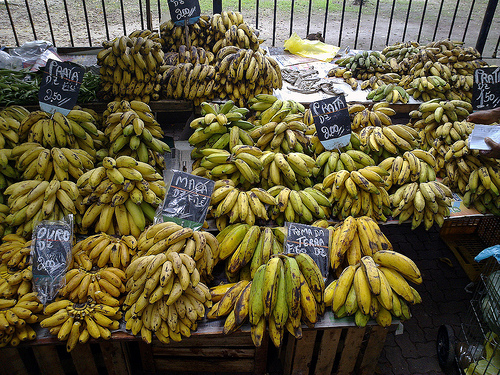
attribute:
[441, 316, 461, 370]
wheel — black, rubber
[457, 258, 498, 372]
prongs — metal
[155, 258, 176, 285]
spot — brown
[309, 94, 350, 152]
sign — black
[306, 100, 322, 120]
letter — white, m, written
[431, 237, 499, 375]
cart — shopping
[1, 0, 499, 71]
gate — metallic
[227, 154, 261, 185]
banana — green, yellow, over ripe, bruised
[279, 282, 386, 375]
crate — wooden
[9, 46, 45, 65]
bag — plastic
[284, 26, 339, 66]
bag — yeellow